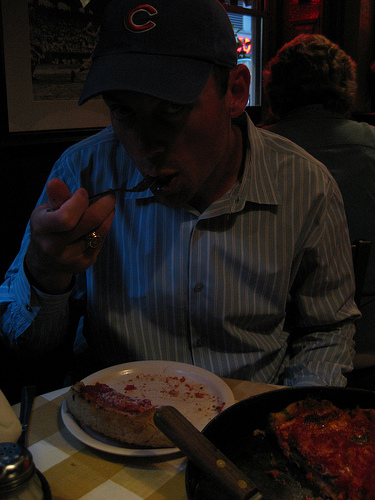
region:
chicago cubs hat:
[109, 8, 160, 39]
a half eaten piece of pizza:
[87, 358, 217, 458]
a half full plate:
[103, 365, 231, 429]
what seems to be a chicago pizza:
[213, 405, 356, 476]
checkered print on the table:
[65, 448, 126, 498]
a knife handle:
[142, 395, 255, 498]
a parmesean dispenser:
[5, 432, 69, 498]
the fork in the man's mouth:
[90, 181, 188, 208]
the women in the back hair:
[271, 32, 363, 137]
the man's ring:
[53, 232, 121, 251]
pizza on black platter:
[207, 364, 372, 494]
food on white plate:
[74, 355, 205, 457]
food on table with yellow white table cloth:
[12, 380, 242, 498]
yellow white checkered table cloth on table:
[27, 361, 311, 494]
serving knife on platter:
[141, 380, 280, 497]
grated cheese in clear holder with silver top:
[6, 427, 60, 498]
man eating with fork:
[76, 59, 293, 233]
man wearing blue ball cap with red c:
[59, 6, 298, 141]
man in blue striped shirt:
[30, 171, 357, 386]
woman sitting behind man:
[220, 14, 373, 144]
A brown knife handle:
[155, 407, 262, 499]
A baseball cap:
[75, 2, 241, 97]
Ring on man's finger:
[72, 219, 113, 261]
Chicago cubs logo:
[108, 1, 190, 55]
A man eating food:
[18, 0, 230, 286]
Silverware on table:
[10, 386, 43, 453]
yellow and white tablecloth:
[45, 446, 185, 498]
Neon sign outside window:
[221, 30, 256, 61]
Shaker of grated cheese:
[1, 440, 55, 498]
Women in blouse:
[259, 36, 373, 252]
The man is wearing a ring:
[2, 0, 346, 376]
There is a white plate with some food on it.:
[56, 352, 239, 469]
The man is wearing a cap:
[17, 29, 353, 369]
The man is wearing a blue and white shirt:
[0, 12, 358, 380]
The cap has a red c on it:
[76, 4, 257, 116]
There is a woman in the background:
[241, 29, 373, 207]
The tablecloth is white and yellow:
[10, 371, 316, 499]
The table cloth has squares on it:
[4, 364, 244, 498]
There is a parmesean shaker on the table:
[4, 441, 57, 499]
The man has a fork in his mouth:
[34, 1, 346, 391]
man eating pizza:
[31, 141, 298, 458]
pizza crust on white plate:
[66, 342, 227, 464]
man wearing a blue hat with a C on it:
[57, 0, 263, 135]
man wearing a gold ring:
[66, 217, 108, 267]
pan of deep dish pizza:
[156, 367, 372, 497]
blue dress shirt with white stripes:
[18, 136, 354, 346]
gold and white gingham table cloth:
[60, 456, 137, 497]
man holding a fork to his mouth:
[36, 147, 215, 283]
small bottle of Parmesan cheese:
[3, 434, 55, 498]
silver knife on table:
[13, 384, 43, 458]